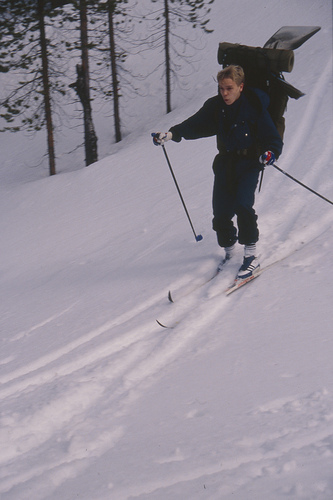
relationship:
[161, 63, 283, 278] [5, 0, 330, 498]
skier on mountain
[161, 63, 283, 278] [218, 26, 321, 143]
skier wearing backpack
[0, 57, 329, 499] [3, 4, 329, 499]
stracks on snow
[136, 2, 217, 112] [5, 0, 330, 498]
tree on mountain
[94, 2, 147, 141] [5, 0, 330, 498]
tree on mountain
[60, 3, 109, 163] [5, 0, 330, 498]
tree on mountain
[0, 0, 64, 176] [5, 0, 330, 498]
tree on mountain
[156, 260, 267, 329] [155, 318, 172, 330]
ski has tip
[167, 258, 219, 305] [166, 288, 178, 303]
ski has tip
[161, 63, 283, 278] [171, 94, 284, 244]
skier wearing skisuit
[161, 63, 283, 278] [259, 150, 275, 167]
skier wearing glove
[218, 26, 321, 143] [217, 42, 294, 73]
backpack has bedroll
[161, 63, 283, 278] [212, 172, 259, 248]
skier wearing pants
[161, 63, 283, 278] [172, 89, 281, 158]
skier wearing jacket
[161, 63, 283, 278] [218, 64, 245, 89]
skier has hair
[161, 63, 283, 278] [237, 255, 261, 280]
skier wearing boot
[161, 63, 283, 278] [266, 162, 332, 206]
skier holding pole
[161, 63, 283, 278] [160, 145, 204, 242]
skier holding pole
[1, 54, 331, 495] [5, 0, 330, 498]
tracks on mountain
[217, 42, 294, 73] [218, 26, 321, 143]
bedroll on backpack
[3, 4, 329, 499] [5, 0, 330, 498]
snow on mountain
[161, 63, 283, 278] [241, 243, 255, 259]
skier has sock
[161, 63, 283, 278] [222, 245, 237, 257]
skier has sock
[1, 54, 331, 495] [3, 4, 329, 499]
tracks on snow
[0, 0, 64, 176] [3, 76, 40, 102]
tree has branch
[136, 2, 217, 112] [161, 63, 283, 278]
tree behind skier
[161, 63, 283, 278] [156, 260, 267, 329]
skier has ski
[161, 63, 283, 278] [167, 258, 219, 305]
skier has ski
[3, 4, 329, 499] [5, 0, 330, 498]
snow covering mountain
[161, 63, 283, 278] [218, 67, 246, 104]
skier has head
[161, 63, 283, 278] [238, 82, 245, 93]
skier has ear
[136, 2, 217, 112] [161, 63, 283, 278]
tree away from skier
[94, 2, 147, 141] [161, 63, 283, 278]
tree away from skier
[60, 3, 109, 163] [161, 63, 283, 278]
tree away from skier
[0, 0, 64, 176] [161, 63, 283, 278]
tree away from skier